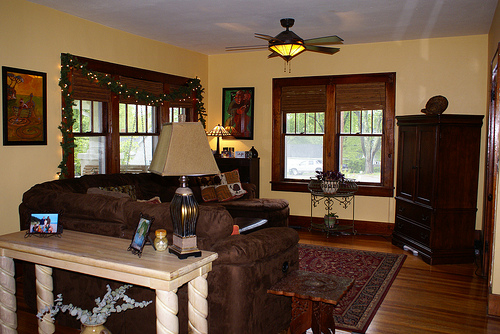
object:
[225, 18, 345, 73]
fan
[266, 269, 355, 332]
end table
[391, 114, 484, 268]
cabinet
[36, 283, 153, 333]
floral arrangment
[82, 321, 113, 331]
vase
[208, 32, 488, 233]
wall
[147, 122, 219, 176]
tan shade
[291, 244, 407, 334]
rug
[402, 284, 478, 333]
floor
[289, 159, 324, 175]
car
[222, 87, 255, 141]
frame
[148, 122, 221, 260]
lamp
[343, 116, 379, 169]
tree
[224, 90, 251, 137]
painting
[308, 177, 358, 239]
stand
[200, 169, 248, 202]
pillow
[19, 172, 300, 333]
couch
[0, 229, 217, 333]
stand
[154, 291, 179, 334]
legs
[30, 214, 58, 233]
photos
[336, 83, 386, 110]
blind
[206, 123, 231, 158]
lamp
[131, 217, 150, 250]
picture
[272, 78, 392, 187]
window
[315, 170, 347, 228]
plant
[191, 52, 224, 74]
corner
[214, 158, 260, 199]
desk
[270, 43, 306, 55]
light